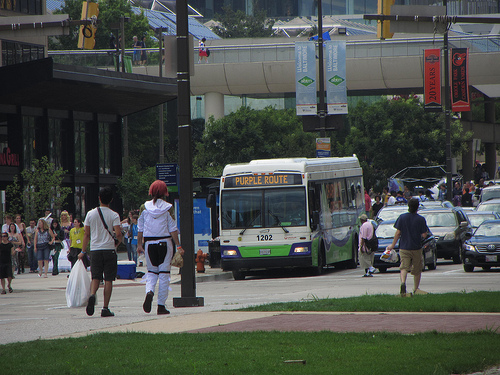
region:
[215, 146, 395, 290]
large city bus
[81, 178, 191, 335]
couple walking down sidewalk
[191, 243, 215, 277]
red fire hydrate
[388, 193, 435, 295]
man walking down sidewalk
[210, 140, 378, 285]
person boarding city bus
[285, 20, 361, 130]
blue advertising banner hanging on pole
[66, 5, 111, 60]
yellow stoplight hanging over street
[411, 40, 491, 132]
red advertising banner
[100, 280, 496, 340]
brick city sidewalk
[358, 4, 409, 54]
yellow stoplight hanging over city street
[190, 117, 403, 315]
green and white bus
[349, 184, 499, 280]
cars parked at intersection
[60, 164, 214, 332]
people walking on side walk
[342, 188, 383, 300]
man crossing street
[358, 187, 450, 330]
man walking across street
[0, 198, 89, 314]
people walking on side walk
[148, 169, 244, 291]
blue and white bus stand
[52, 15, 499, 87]
bridge over road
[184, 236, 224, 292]
red fire extinguisher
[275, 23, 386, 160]
flags on pole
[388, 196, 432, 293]
brown haired man walking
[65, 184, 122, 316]
brown haired man walking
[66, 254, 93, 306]
large white trash bag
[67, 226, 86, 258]
yellowish green shirt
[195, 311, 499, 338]
maroon brick walkway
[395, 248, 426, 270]
tan cargo shorts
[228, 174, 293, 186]
orange lit Purple Route bus sign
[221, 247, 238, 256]
rectangle bus headlight lit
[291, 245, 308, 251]
rectangle plastic bus headlight lit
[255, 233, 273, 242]
black bus number 1202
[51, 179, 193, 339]
Two people walking down the street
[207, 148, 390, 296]
A white bus with blue and green accents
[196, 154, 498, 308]
Motor vehicles driving down the street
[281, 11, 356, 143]
Street signs on the post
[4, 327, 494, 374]
Grass on the ground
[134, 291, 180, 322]
A pair of black shoes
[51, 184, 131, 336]
A man carrying a plastic bag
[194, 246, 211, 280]
A red fire hydrant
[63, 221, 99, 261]
A yellow t shirt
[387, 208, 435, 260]
A blue t shirt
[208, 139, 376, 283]
Bus is white and green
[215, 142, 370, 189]
Roof of bus is white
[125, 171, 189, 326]
Person wearing white cloths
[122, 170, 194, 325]
Person has a red hat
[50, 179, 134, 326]
Person carrying a white bag in his left hand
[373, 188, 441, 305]
Person walking in the green grass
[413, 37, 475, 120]
red banners in a pole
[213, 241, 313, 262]
Headlights of bus are on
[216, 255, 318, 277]
Bumper of bus is black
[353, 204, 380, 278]
Old lady approaching a bus